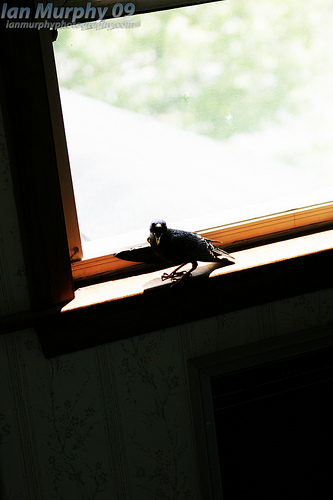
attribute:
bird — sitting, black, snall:
[145, 220, 236, 288]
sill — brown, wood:
[1, 197, 332, 336]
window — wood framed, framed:
[2, 1, 332, 359]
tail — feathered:
[207, 239, 236, 266]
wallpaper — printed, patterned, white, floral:
[0, 135, 331, 500]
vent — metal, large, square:
[185, 320, 332, 500]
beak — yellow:
[153, 234, 163, 245]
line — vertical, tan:
[94, 340, 138, 500]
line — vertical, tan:
[4, 328, 41, 499]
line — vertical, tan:
[175, 319, 201, 362]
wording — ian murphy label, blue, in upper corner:
[2, 1, 142, 30]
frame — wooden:
[1, 1, 76, 310]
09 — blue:
[111, 1, 138, 18]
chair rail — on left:
[0, 309, 35, 336]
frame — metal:
[39, 27, 84, 263]